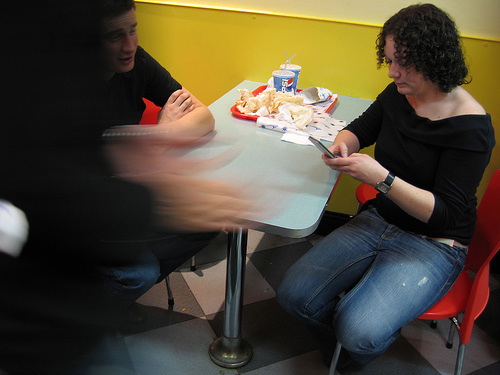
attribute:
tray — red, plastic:
[231, 79, 341, 124]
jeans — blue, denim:
[328, 214, 485, 355]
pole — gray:
[216, 222, 261, 367]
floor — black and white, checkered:
[78, 206, 499, 373]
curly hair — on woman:
[368, 22, 479, 101]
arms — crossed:
[88, 55, 220, 162]